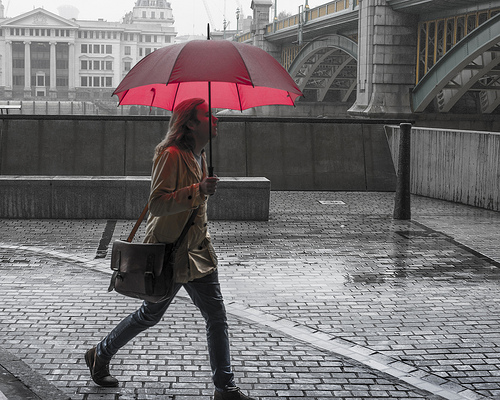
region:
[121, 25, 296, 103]
a red umbrella that is open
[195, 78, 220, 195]
a person holding an umbrella handle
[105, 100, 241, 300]
a man carrying a brown leather bag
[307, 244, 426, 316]
a brick walk way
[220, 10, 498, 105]
a metal and stone bridge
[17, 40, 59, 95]
pillars on the outside of a building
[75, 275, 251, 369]
brown leather pants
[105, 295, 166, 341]
a person's right leg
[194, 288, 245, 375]
a person's left leg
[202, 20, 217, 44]
the tip on an umbrella top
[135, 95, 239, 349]
this is a lady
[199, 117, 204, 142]
the lady is light skinned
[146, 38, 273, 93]
this is a umbrella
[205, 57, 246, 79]
the umbrella is red in color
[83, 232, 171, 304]
this is a bag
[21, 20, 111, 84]
this is a building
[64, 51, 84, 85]
the wall is white in color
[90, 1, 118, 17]
this is the sky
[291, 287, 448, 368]
this is the ground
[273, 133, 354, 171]
this is a wall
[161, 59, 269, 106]
This man is carrying a very red umbrella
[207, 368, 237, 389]
This man has very brown shoes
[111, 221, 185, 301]
This man has a very brown messenger bag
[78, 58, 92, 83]
This building has very white details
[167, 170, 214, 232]
This man is wearing a khaki colored jacket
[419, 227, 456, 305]
There is rain on the sidewalk here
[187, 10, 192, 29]
There is a piece of white sky that is in the distance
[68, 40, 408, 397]
Jackson Mingus took this photo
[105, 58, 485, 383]
This is a photo from Europe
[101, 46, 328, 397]
This is a photo from France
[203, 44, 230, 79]
the umbrella is red in color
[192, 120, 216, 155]
the lady is light skinned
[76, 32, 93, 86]
this is the wall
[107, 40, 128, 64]
the wall is white in color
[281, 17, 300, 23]
the wall is brown in color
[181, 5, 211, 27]
this is the sky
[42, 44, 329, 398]
person walking on the sidewalk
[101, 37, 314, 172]
head is under the red umbrella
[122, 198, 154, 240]
strap from the bag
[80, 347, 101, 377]
heel is lifted off the ground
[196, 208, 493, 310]
puddles of water on the sidewalk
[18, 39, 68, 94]
two white columns on the front of the building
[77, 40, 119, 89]
windows on the side of the building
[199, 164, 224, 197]
hand wrapped around the umbrella rod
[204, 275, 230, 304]
wrinkles in the pants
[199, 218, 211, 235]
black button on the jacket